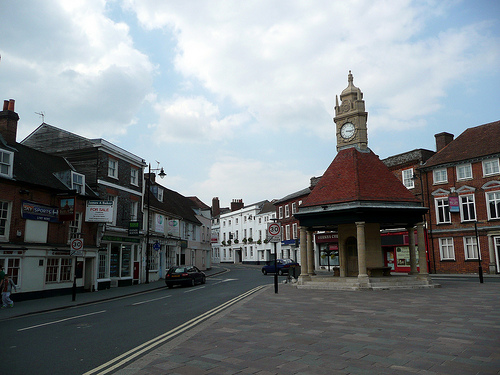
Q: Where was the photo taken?
A: Center of town.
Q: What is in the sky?
A: Clouds.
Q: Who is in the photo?
A: No body.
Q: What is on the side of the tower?
A: Clock.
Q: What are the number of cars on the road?
A: 2.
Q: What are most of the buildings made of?
A: Brick.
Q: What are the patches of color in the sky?
A: Blue.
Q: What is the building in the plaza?
A: Gazebo.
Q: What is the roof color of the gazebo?
A: Red.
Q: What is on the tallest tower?
A: A clock.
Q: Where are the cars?
A: On the street.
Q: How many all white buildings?
A: One.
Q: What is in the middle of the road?
A: White lines.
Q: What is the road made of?
A: Asphalt.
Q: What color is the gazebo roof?
A: Red.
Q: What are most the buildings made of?
A: Brick.